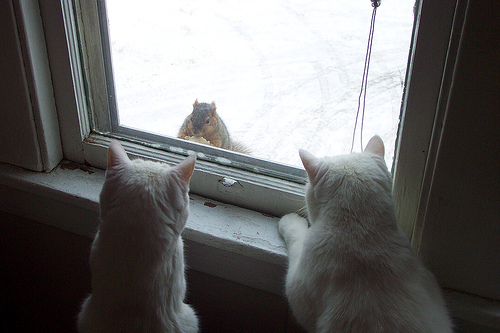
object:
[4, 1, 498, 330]
house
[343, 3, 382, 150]
strings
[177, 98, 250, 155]
rodent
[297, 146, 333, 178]
ear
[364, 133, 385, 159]
ear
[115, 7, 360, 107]
snow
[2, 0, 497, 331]
scene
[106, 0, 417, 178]
window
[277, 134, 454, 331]
cat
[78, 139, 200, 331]
cats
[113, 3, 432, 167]
outside